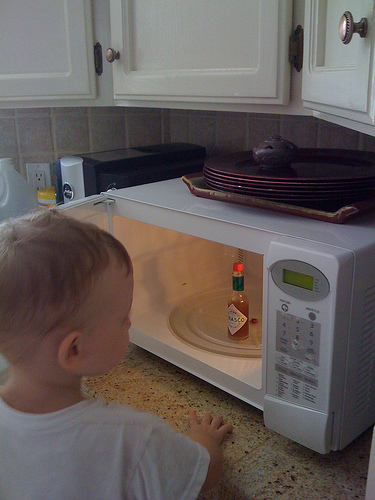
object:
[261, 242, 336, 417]
control panel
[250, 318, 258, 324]
crumb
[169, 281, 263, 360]
plate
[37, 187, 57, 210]
container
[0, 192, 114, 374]
door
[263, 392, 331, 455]
button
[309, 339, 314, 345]
nine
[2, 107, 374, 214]
backsplash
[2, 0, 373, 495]
kitchen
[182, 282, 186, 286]
food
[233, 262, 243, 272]
lid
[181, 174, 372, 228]
tray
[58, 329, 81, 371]
ear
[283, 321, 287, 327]
number four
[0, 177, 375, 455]
microwave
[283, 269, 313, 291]
blank display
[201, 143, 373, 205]
plates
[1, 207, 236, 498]
child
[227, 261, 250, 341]
tabasco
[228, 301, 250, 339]
hot sauce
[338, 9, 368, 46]
knob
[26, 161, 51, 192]
outlet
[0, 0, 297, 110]
cabinet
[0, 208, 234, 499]
boy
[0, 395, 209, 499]
shirt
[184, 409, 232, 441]
hand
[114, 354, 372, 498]
counter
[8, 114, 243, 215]
corner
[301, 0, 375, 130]
cabinet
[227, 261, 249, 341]
bottle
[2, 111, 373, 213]
wall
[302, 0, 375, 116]
door